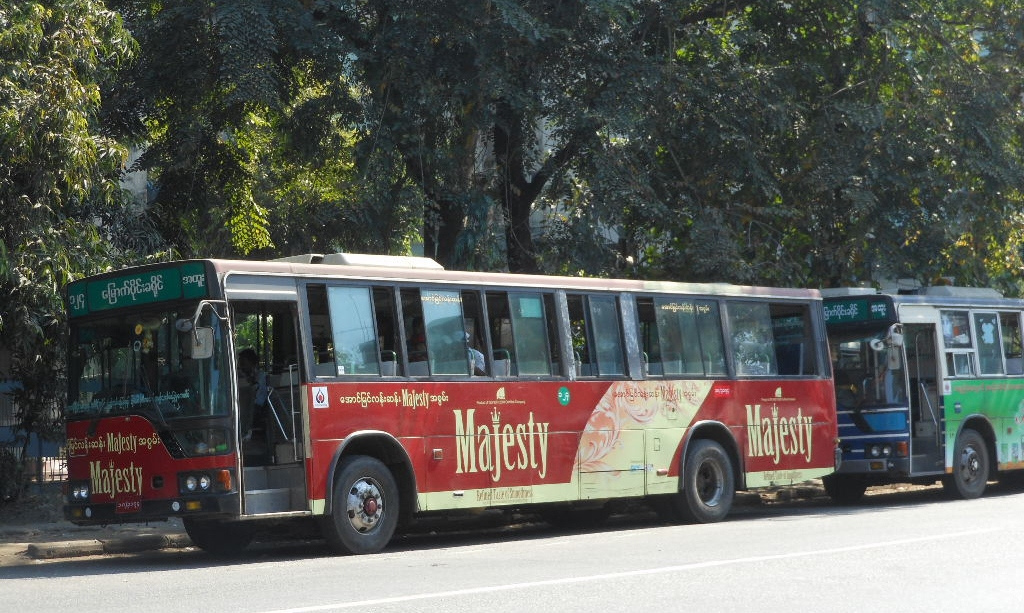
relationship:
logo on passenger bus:
[451, 405, 566, 485] [25, 247, 844, 554]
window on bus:
[488, 290, 566, 375] [57, 245, 840, 555]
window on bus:
[296, 256, 407, 382] [8, 227, 866, 595]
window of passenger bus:
[649, 301, 725, 377] [25, 247, 844, 554]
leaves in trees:
[48, 24, 131, 66] [3, 5, 137, 403]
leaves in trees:
[361, 22, 413, 92] [295, 5, 494, 263]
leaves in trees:
[571, 20, 634, 87] [489, 7, 671, 273]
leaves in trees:
[828, 81, 913, 170] [787, 5, 997, 282]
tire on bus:
[331, 450, 401, 556] [57, 245, 840, 555]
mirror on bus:
[187, 304, 230, 365] [57, 245, 840, 555]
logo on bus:
[451, 405, 566, 485] [57, 245, 840, 555]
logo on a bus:
[451, 405, 566, 485] [57, 245, 840, 555]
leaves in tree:
[789, 7, 906, 85] [649, 0, 917, 251]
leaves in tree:
[673, 173, 760, 247] [623, 102, 812, 269]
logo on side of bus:
[451, 405, 566, 485] [57, 245, 840, 555]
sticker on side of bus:
[550, 384, 576, 404] [57, 245, 840, 555]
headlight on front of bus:
[66, 485, 80, 505] [57, 245, 840, 555]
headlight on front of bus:
[79, 487, 99, 507] [57, 245, 840, 555]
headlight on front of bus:
[184, 472, 200, 498] [57, 245, 840, 555]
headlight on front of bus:
[198, 472, 212, 494] [57, 245, 840, 555]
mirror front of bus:
[187, 304, 229, 365] [57, 245, 840, 555]